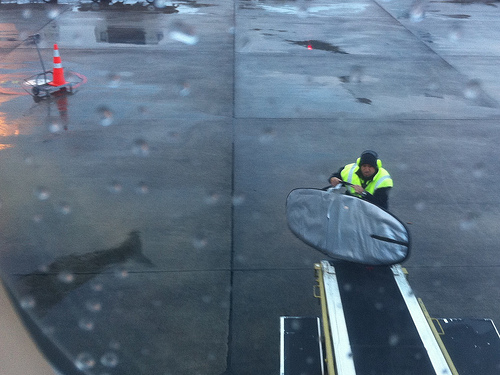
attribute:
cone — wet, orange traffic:
[49, 36, 81, 84]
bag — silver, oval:
[285, 179, 415, 269]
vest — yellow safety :
[340, 165, 388, 197]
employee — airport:
[327, 149, 394, 211]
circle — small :
[59, 266, 75, 285]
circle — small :
[64, 334, 100, 374]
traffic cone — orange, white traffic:
[44, 40, 64, 85]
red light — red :
[302, 40, 314, 50]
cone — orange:
[39, 35, 71, 90]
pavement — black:
[123, 62, 463, 142]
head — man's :
[353, 147, 383, 183]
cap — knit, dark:
[358, 150, 378, 172]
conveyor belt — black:
[309, 232, 465, 372]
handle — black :
[23, 35, 51, 85]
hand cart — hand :
[23, 30, 73, 97]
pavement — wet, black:
[215, 14, 452, 149]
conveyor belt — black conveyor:
[326, 263, 448, 373]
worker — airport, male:
[327, 150, 393, 215]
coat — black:
[327, 160, 391, 209]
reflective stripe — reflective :
[345, 161, 356, 183]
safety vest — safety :
[338, 157, 393, 198]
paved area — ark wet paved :
[257, 17, 404, 119]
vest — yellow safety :
[334, 164, 386, 195]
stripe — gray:
[52, 48, 60, 55]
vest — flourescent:
[320, 152, 390, 202]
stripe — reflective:
[37, 46, 75, 61]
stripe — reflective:
[45, 41, 63, 62]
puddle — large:
[49, 14, 199, 63]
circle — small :
[284, 177, 415, 274]